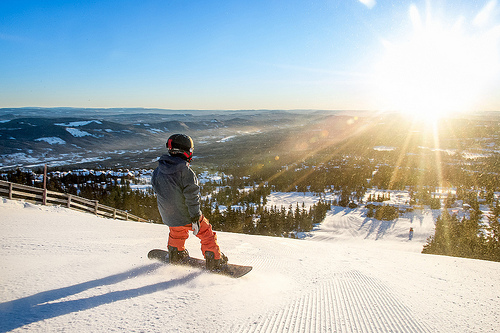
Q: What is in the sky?
A: Sun.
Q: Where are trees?
A: In the distance.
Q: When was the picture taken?
A: Daytime.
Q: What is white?
A: Snow.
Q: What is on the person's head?
A: Helmet.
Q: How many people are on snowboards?
A: One.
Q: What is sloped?
A: A hill.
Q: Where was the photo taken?
A: Ski slope.